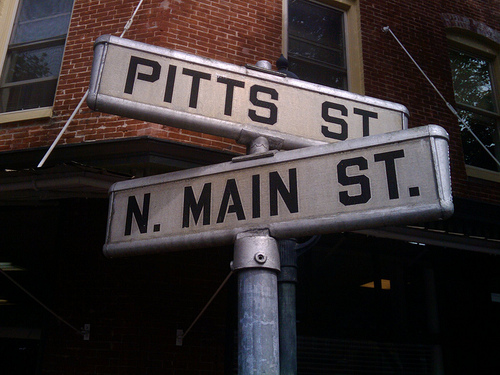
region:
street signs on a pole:
[76, 23, 478, 263]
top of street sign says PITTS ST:
[85, 31, 421, 158]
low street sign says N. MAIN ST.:
[99, 125, 464, 258]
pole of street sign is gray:
[223, 235, 285, 370]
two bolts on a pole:
[223, 250, 269, 270]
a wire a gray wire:
[370, 1, 495, 166]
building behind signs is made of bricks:
[5, 5, 497, 366]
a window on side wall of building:
[2, 0, 87, 126]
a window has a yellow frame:
[265, 0, 372, 96]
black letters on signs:
[91, 28, 461, 268]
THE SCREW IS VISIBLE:
[249, 253, 258, 264]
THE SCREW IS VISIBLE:
[254, 248, 268, 269]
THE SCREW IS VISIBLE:
[249, 248, 264, 262]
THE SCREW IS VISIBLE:
[260, 248, 264, 261]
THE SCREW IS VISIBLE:
[257, 240, 264, 288]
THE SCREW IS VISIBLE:
[247, 251, 269, 283]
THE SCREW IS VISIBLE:
[249, 248, 278, 276]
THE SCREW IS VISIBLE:
[261, 239, 268, 276]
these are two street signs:
[96, 36, 458, 251]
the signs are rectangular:
[98, 37, 415, 156]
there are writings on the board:
[127, 51, 358, 146]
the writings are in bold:
[186, 65, 283, 120]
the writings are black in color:
[246, 85, 256, 102]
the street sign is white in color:
[288, 101, 313, 123]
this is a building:
[180, 7, 282, 46]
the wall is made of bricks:
[191, 15, 246, 45]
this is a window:
[7, 4, 57, 105]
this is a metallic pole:
[237, 277, 270, 372]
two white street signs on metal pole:
[70, 12, 494, 230]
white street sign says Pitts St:
[100, 37, 332, 148]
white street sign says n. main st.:
[82, 147, 454, 249]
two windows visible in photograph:
[0, 5, 395, 135]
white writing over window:
[448, 14, 493, 38]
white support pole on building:
[54, 7, 178, 159]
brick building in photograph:
[54, 1, 432, 158]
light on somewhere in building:
[357, 247, 418, 305]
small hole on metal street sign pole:
[227, 240, 281, 275]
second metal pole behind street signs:
[245, 52, 357, 373]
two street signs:
[87, 35, 447, 240]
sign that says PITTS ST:
[105, 45, 385, 140]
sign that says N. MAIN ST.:
[96, 145, 421, 240]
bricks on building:
[170, 2, 260, 42]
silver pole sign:
[235, 267, 280, 368]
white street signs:
[91, 32, 453, 243]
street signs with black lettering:
[91, 33, 453, 235]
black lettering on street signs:
[90, 36, 447, 244]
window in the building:
[3, 0, 70, 119]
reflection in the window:
[451, 50, 491, 103]